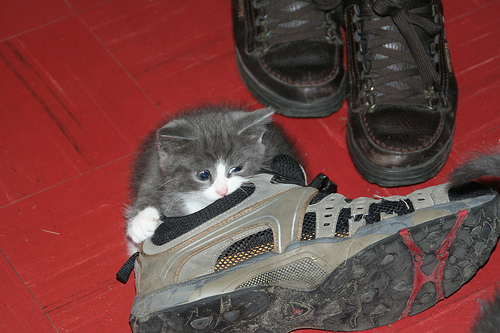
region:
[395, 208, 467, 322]
Red X on the bottom of a shoe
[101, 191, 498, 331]
Sole on a sideways shoe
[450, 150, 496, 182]
Black cat tail on a shoe tip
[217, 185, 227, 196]
Pink nose on a cat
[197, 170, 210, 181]
Large eye on a kitten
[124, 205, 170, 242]
White kitten paw on a shoe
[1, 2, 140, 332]
Red tiled floor under a shoe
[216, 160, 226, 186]
White fur on a kitten's nose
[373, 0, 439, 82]
Brown shoe lace on a shoe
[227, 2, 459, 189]
Two brown shoes on a red floor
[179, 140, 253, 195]
the face of a cat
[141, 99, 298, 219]
a gray and white cat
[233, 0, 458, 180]
a pair of boots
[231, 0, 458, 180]
the boots are brown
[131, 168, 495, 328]
the shoe has dirt on it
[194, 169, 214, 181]
the eye of a cat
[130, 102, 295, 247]
the cat is near a shoe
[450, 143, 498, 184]
a gray cat's tail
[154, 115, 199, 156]
the ear of a kitten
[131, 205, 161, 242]
the paw of a cat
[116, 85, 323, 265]
small grey and white kitten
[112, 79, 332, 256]
kitten chewing on tennis shoe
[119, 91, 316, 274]
grey and white kitten with blue eyes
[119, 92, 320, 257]
tiny four legged mammal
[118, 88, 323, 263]
kitten sitting on red laminated floor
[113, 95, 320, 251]
small furry domesticated feline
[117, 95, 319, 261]
tiny pet kitten with no collar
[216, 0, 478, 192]
dark brown shoes with black soles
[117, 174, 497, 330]
grey and black tennis shoe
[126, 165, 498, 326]
tennis shoe with red designs on the sole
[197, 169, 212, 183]
wide blue eye of cat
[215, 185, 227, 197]
pink nose of cat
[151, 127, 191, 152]
grey right ear of cat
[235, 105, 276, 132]
grey left ear of cat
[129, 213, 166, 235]
white pay of cat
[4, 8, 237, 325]
red floor under cat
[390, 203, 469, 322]
red part of shoe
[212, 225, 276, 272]
black mesh on shoe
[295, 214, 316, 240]
black mesh on shoe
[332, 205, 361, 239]
black mesh on shoe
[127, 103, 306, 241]
grey and white kitten in a shoe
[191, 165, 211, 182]
blue eye of grey kitten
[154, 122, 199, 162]
right ear of grey kitten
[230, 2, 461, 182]
pair of black shoes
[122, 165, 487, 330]
grey tennis shoe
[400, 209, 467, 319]
red symbol on bottom of grey shoe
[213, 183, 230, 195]
pink nose on grey kitten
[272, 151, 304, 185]
black tongue on grey shoe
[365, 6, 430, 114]
black laces on black shoe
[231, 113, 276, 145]
left eat of grey kitten